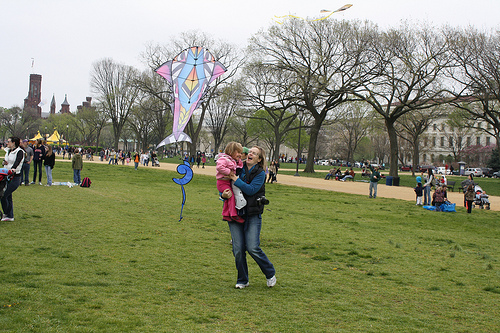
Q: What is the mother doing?
A: Holding child.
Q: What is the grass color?
A: Green.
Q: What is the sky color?
A: Blue.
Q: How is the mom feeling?
A: Happy.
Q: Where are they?
A: Park.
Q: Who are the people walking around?
A: Pedestrians.